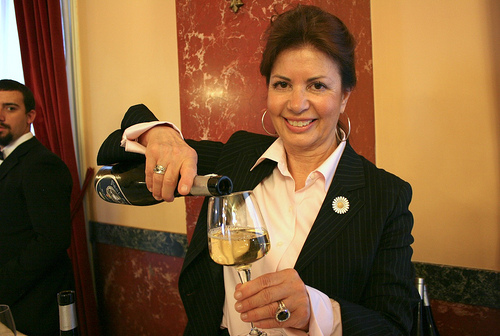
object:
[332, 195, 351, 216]
daisy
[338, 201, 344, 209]
yellow center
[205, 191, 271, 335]
glass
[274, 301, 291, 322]
ring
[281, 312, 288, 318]
stone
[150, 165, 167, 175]
bands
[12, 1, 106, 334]
curtain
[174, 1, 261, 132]
marble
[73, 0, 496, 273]
wall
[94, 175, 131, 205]
label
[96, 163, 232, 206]
bottle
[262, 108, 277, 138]
earing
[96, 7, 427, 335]
woman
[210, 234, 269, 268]
wine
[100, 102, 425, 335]
jacket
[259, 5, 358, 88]
hair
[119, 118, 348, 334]
shirt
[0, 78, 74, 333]
man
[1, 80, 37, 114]
hair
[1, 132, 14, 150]
beard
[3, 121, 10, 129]
mustache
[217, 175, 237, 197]
top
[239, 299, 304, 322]
finger